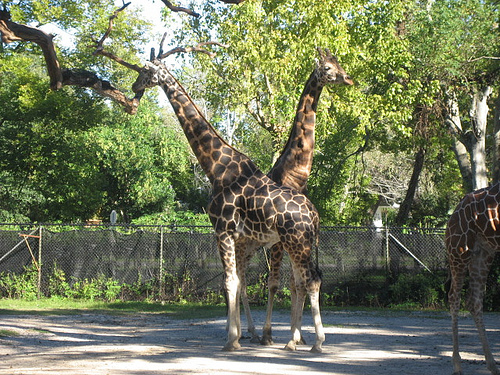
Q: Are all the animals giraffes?
A: Yes, all the animals are giraffes.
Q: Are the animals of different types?
A: No, all the animals are giraffes.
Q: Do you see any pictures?
A: No, there are no pictures.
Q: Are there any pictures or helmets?
A: No, there are no pictures or helmets.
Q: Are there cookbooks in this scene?
A: No, there are no cookbooks.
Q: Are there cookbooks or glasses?
A: No, there are no cookbooks or glasses.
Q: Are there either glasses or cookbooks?
A: No, there are no cookbooks or glasses.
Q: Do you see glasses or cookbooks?
A: No, there are no cookbooks or glasses.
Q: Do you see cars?
A: No, there are no cars.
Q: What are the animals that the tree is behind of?
A: The animals are giraffes.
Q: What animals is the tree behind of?
A: The tree is behind the giraffes.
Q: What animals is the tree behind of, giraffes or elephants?
A: The tree is behind giraffes.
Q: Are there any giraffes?
A: Yes, there are giraffes.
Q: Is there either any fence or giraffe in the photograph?
A: Yes, there are giraffes.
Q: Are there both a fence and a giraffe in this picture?
A: Yes, there are both a giraffe and a fence.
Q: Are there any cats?
A: No, there are no cats.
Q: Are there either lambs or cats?
A: No, there are no cats or lambs.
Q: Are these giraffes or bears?
A: These are giraffes.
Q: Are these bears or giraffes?
A: These are giraffes.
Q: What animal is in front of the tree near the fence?
A: The giraffes are in front of the tree.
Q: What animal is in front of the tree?
A: The giraffes are in front of the tree.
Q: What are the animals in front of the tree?
A: The animals are giraffes.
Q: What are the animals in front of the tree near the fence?
A: The animals are giraffes.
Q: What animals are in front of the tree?
A: The animals are giraffes.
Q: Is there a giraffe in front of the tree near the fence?
A: Yes, there are giraffes in front of the tree.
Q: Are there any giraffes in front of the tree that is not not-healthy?
A: Yes, there are giraffes in front of the tree.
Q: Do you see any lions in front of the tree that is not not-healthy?
A: No, there are giraffes in front of the tree.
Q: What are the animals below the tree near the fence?
A: The animals are giraffes.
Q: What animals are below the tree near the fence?
A: The animals are giraffes.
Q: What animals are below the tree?
A: The animals are giraffes.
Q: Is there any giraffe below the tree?
A: Yes, there are giraffes below the tree.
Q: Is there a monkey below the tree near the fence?
A: No, there are giraffes below the tree.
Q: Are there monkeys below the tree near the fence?
A: No, there are giraffes below the tree.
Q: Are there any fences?
A: Yes, there is a fence.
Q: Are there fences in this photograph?
A: Yes, there is a fence.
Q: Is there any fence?
A: Yes, there is a fence.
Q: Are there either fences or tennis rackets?
A: Yes, there is a fence.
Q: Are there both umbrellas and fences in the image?
A: No, there is a fence but no umbrellas.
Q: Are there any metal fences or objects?
A: Yes, there is a metal fence.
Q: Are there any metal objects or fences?
A: Yes, there is a metal fence.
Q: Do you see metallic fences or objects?
A: Yes, there is a metal fence.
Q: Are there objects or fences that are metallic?
A: Yes, the fence is metallic.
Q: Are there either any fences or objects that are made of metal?
A: Yes, the fence is made of metal.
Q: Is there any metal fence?
A: Yes, there is a fence that is made of metal.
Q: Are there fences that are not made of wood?
A: Yes, there is a fence that is made of metal.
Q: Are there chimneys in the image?
A: No, there are no chimneys.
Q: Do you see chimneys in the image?
A: No, there are no chimneys.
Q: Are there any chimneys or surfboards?
A: No, there are no chimneys or surfboards.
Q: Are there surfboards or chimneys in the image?
A: No, there are no chimneys or surfboards.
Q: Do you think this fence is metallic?
A: Yes, the fence is metallic.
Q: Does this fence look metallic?
A: Yes, the fence is metallic.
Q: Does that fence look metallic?
A: Yes, the fence is metallic.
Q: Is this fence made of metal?
A: Yes, the fence is made of metal.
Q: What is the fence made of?
A: The fence is made of metal.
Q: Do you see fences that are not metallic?
A: No, there is a fence but it is metallic.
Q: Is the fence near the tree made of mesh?
A: No, the fence is made of metal.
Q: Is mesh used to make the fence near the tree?
A: No, the fence is made of metal.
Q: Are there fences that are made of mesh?
A: No, there is a fence but it is made of metal.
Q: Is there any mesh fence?
A: No, there is a fence but it is made of metal.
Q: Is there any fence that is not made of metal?
A: No, there is a fence but it is made of metal.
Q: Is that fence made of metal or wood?
A: The fence is made of metal.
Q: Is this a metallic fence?
A: Yes, this is a metallic fence.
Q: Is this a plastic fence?
A: No, this is a metallic fence.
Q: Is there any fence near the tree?
A: Yes, there is a fence near the tree.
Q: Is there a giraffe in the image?
A: Yes, there is a giraffe.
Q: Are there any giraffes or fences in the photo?
A: Yes, there is a giraffe.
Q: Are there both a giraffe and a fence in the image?
A: Yes, there are both a giraffe and a fence.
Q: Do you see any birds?
A: No, there are no birds.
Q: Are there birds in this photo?
A: No, there are no birds.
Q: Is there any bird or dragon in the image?
A: No, there are no birds or dragons.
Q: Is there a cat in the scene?
A: No, there are no cats.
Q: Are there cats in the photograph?
A: No, there are no cats.